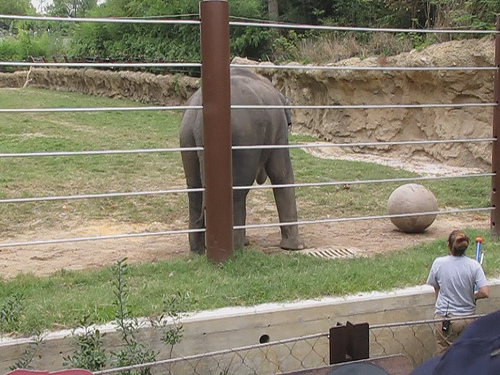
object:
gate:
[278, 350, 423, 374]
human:
[423, 227, 492, 359]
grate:
[292, 243, 364, 262]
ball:
[383, 181, 439, 234]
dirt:
[0, 186, 493, 287]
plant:
[6, 326, 53, 374]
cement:
[0, 275, 499, 375]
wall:
[0, 276, 499, 374]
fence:
[0, 0, 499, 268]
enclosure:
[0, 271, 499, 375]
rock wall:
[230, 34, 499, 174]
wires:
[226, 19, 500, 36]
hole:
[256, 333, 271, 347]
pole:
[196, 0, 239, 265]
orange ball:
[474, 235, 484, 244]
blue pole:
[473, 240, 483, 264]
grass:
[0, 224, 499, 343]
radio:
[441, 300, 451, 333]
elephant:
[177, 64, 307, 256]